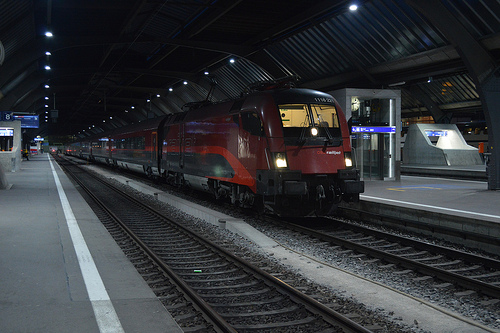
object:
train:
[62, 87, 366, 223]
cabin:
[242, 90, 355, 204]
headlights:
[269, 151, 288, 171]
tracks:
[53, 154, 500, 333]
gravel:
[227, 234, 331, 270]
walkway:
[0, 145, 188, 333]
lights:
[35, 28, 57, 124]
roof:
[20, 5, 163, 140]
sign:
[350, 124, 399, 135]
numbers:
[314, 97, 334, 103]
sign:
[7, 112, 41, 128]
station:
[0, 0, 499, 333]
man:
[21, 152, 29, 161]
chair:
[21, 152, 29, 161]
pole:
[387, 99, 395, 181]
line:
[41, 152, 127, 332]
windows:
[281, 99, 343, 134]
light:
[309, 127, 319, 138]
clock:
[350, 96, 361, 112]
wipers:
[317, 114, 335, 145]